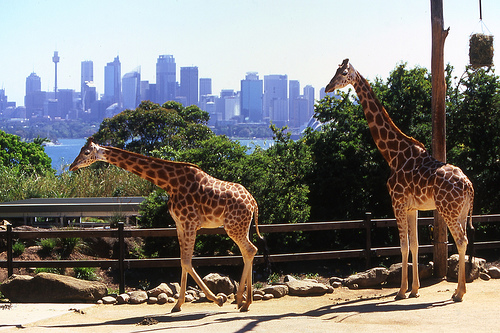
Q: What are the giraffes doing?
A: Walking.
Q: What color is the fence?
A: Brown.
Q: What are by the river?
A: Buildings.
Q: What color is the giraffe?
A: Brown.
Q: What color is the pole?
A: Brown.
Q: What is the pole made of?
A: Wood.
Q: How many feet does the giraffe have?
A: Four.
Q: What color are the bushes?
A: Green.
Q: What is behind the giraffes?
A: The city.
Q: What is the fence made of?
A: Wood.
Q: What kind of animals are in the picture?
A: Giraffes.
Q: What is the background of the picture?
A: A city.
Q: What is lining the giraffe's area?
A: A fence.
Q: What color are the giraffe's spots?
A: Brown.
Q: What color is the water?
A: Blue.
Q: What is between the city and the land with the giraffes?
A: A water body.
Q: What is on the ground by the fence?
A: Rocks.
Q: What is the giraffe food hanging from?
A: A pole.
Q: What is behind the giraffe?
A: A fence.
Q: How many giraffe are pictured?
A: Two.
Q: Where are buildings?
A: In the distance.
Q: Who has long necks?
A: The giraffe.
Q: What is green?
A: Trees.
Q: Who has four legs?
A: One giraffe.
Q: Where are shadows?
A: On the ground.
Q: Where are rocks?
A: Along the path.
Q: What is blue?
A: Sky.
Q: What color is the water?
A: Blue.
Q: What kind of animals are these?
A: Giraffes.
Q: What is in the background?
A: A city skyline.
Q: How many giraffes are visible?
A: Two.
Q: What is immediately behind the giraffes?
A: A fence.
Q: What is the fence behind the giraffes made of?
A: Wood.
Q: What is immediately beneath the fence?
A: Rocks.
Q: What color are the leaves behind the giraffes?
A: Green.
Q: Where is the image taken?
A: A zoo.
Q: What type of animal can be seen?
A: Giraffe.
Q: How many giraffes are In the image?
A: Two.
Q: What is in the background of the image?
A: A city skyline.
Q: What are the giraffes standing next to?
A: A railing.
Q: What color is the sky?
A: Light blue.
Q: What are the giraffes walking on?
A: Dirt.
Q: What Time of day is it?
A: Daytime.